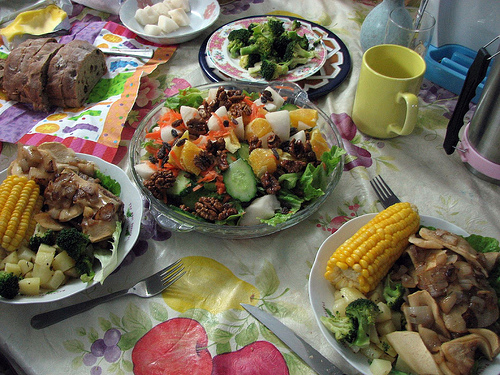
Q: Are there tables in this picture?
A: Yes, there is a table.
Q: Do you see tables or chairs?
A: Yes, there is a table.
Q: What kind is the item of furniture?
A: The piece of furniture is a table.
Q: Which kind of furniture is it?
A: The piece of furniture is a table.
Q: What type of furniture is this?
A: This is a table.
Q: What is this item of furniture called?
A: This is a table.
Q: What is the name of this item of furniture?
A: This is a table.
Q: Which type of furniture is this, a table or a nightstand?
A: This is a table.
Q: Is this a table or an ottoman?
A: This is a table.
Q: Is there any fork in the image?
A: Yes, there is a fork.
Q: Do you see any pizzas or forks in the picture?
A: Yes, there is a fork.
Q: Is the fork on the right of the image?
A: No, the fork is on the left of the image.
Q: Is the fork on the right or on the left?
A: The fork is on the left of the image.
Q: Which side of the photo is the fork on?
A: The fork is on the left of the image.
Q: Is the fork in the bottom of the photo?
A: Yes, the fork is in the bottom of the image.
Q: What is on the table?
A: The fork is on the table.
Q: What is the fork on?
A: The fork is on the table.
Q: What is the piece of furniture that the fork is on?
A: The piece of furniture is a table.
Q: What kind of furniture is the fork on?
A: The fork is on the table.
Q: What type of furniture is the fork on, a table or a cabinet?
A: The fork is on a table.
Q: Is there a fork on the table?
A: Yes, there is a fork on the table.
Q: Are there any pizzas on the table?
A: No, there is a fork on the table.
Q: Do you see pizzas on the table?
A: No, there is a fork on the table.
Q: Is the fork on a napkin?
A: No, the fork is on a table.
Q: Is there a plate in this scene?
A: Yes, there is a plate.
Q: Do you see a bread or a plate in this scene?
A: Yes, there is a plate.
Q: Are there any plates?
A: Yes, there is a plate.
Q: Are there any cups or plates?
A: Yes, there is a plate.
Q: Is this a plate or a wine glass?
A: This is a plate.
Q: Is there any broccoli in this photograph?
A: Yes, there is broccoli.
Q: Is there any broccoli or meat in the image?
A: Yes, there is broccoli.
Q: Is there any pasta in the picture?
A: No, there is no pasta.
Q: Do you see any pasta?
A: No, there is no pasta.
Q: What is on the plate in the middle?
A: The broccoli is on the plate.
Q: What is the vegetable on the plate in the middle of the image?
A: The vegetable is broccoli.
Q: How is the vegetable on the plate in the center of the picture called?
A: The vegetable is broccoli.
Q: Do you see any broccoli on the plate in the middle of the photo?
A: Yes, there is broccoli on the plate.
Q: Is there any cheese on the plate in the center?
A: No, there is broccoli on the plate.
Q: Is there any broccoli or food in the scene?
A: Yes, there is broccoli.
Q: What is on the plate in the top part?
A: The broccoli is on the plate.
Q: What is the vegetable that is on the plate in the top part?
A: The vegetable is broccoli.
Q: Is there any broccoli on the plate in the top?
A: Yes, there is broccoli on the plate.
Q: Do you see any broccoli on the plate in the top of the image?
A: Yes, there is broccoli on the plate.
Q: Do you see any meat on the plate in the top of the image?
A: No, there is broccoli on the plate.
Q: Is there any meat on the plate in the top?
A: No, there is broccoli on the plate.